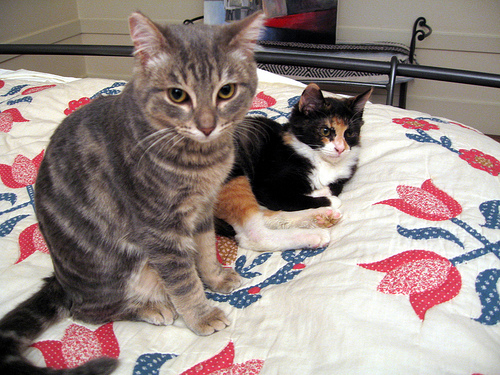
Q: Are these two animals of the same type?
A: Yes, all the animals are cats.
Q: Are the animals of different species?
A: No, all the animals are cats.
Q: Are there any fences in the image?
A: No, there are no fences.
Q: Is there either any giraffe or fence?
A: No, there are no fences or giraffes.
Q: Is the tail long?
A: Yes, the tail is long.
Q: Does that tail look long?
A: Yes, the tail is long.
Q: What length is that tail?
A: The tail is long.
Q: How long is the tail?
A: The tail is long.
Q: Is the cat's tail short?
A: No, the tail is long.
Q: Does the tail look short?
A: No, the tail is long.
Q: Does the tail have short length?
A: No, the tail is long.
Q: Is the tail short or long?
A: The tail is long.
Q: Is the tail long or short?
A: The tail is long.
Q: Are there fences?
A: No, there are no fences.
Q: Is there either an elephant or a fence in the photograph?
A: No, there are no fences or elephants.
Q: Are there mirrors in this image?
A: No, there are no mirrors.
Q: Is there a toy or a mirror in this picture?
A: No, there are no mirrors or toys.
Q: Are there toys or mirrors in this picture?
A: No, there are no mirrors or toys.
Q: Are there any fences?
A: No, there are no fences.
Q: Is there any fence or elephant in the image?
A: No, there are no fences or elephants.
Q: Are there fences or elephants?
A: No, there are no fences or elephants.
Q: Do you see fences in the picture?
A: No, there are no fences.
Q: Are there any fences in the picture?
A: No, there are no fences.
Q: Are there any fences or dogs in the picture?
A: No, there are no fences or dogs.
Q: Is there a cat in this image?
A: Yes, there is a cat.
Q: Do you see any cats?
A: Yes, there is a cat.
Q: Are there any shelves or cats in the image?
A: Yes, there is a cat.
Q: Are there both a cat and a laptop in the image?
A: No, there is a cat but no laptops.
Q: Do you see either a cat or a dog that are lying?
A: Yes, the cat is lying.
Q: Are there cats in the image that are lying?
A: Yes, there is a cat that is lying.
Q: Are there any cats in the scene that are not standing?
A: Yes, there is a cat that is lying.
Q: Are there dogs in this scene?
A: No, there are no dogs.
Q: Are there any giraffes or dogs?
A: No, there are no dogs or giraffes.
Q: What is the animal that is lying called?
A: The animal is a cat.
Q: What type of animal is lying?
A: The animal is a cat.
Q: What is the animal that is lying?
A: The animal is a cat.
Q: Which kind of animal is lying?
A: The animal is a cat.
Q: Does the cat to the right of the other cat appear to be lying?
A: Yes, the cat is lying.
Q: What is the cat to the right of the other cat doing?
A: The cat is lying.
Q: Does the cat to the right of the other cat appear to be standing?
A: No, the cat is lying.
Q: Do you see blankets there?
A: Yes, there is a blanket.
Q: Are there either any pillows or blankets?
A: Yes, there is a blanket.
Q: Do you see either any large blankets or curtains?
A: Yes, there is a large blanket.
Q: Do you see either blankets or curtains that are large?
A: Yes, the blanket is large.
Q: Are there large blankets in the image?
A: Yes, there is a large blanket.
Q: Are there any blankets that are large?
A: Yes, there is a blanket that is large.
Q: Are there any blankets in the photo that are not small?
A: Yes, there is a large blanket.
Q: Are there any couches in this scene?
A: No, there are no couches.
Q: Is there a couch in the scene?
A: No, there are no couches.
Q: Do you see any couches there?
A: No, there are no couches.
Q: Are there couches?
A: No, there are no couches.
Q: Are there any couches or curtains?
A: No, there are no couches or curtains.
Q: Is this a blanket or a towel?
A: This is a blanket.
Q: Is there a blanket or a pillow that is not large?
A: No, there is a blanket but it is large.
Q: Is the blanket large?
A: Yes, the blanket is large.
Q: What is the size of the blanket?
A: The blanket is large.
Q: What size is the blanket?
A: The blanket is large.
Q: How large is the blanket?
A: The blanket is large.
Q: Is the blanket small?
A: No, the blanket is large.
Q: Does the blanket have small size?
A: No, the blanket is large.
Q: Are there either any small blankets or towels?
A: No, there is a blanket but it is large.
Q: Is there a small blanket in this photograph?
A: No, there is a blanket but it is large.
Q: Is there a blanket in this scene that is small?
A: No, there is a blanket but it is large.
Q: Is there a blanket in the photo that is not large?
A: No, there is a blanket but it is large.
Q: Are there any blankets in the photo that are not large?
A: No, there is a blanket but it is large.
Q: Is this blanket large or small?
A: The blanket is large.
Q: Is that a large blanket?
A: Yes, that is a large blanket.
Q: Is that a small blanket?
A: No, that is a large blanket.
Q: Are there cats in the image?
A: Yes, there is a cat.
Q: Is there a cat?
A: Yes, there is a cat.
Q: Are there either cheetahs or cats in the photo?
A: Yes, there is a cat.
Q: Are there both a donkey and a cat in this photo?
A: No, there is a cat but no donkeys.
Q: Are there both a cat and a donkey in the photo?
A: No, there is a cat but no donkeys.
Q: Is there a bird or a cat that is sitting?
A: Yes, the cat is sitting.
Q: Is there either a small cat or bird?
A: Yes, there is a small cat.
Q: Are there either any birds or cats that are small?
A: Yes, the cat is small.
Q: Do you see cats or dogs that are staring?
A: Yes, the cat is staring.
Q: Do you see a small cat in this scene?
A: Yes, there is a small cat.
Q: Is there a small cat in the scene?
A: Yes, there is a small cat.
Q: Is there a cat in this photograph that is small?
A: Yes, there is a cat that is small.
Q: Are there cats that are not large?
A: Yes, there is a small cat.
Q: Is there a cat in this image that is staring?
A: Yes, there is a cat that is staring.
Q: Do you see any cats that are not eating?
A: Yes, there is a cat that is staring .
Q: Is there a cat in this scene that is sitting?
A: Yes, there is a cat that is sitting.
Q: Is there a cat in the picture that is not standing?
A: Yes, there is a cat that is sitting.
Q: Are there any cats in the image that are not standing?
A: Yes, there is a cat that is sitting.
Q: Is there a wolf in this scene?
A: No, there are no wolves.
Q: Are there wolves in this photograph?
A: No, there are no wolves.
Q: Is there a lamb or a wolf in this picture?
A: No, there are no wolves or lambs.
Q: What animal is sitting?
A: The animal is a cat.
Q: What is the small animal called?
A: The animal is a cat.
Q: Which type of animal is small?
A: The animal is a cat.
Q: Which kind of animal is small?
A: The animal is a cat.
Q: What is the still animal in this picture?
A: The animal is a cat.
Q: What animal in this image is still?
A: The animal is a cat.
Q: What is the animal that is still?
A: The animal is a cat.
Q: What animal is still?
A: The animal is a cat.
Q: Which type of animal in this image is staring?
A: The animal is a cat.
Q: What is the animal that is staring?
A: The animal is a cat.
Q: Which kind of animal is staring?
A: The animal is a cat.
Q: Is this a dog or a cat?
A: This is a cat.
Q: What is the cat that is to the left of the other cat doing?
A: The cat is sitting.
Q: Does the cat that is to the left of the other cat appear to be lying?
A: No, the cat is sitting.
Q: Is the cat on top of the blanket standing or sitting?
A: The cat is sitting.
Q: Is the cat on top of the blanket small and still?
A: Yes, the cat is small and still.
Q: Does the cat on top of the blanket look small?
A: Yes, the cat is small.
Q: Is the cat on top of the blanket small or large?
A: The cat is small.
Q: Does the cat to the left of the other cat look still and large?
A: No, the cat is still but small.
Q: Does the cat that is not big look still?
A: Yes, the cat is still.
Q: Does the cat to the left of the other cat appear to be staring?
A: Yes, the cat is staring.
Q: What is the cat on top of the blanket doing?
A: The cat is staring.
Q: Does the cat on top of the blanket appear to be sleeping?
A: No, the cat is staring.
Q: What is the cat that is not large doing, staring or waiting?
A: The cat is staring.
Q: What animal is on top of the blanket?
A: The cat is on top of the blanket.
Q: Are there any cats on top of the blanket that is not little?
A: Yes, there is a cat on top of the blanket.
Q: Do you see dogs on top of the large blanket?
A: No, there is a cat on top of the blanket.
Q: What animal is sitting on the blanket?
A: The cat is sitting on the blanket.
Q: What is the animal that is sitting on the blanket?
A: The animal is a cat.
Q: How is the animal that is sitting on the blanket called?
A: The animal is a cat.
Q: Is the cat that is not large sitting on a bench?
A: No, the cat is sitting on a blanket.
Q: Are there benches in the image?
A: No, there are no benches.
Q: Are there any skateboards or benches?
A: No, there are no benches or skateboards.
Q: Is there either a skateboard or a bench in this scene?
A: No, there are no benches or skateboards.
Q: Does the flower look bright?
A: Yes, the flower is bright.